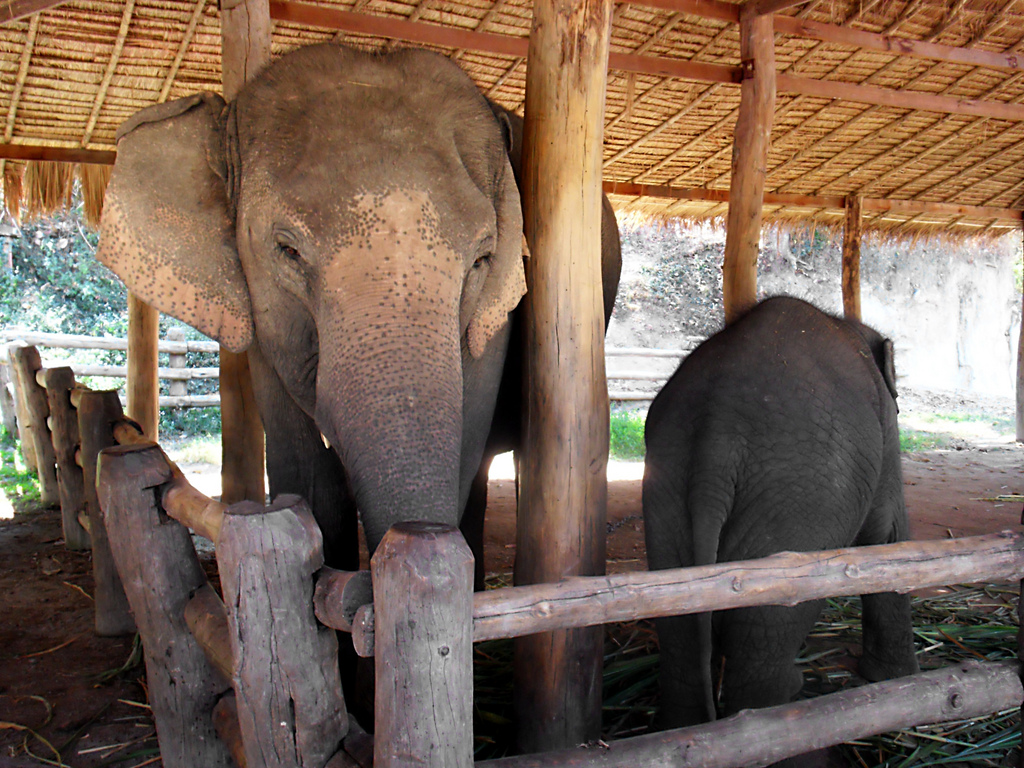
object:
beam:
[0, 207, 1022, 519]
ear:
[96, 91, 254, 354]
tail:
[688, 421, 745, 746]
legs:
[722, 526, 857, 765]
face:
[235, 43, 506, 562]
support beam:
[221, 0, 268, 525]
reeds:
[471, 578, 1019, 767]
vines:
[0, 178, 221, 436]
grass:
[611, 409, 646, 457]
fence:
[0, 331, 1022, 767]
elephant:
[640, 293, 919, 724]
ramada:
[2, 0, 1024, 767]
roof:
[195, 100, 1024, 250]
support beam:
[514, 4, 609, 754]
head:
[95, 43, 528, 558]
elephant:
[95, 39, 623, 729]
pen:
[0, 160, 1021, 767]